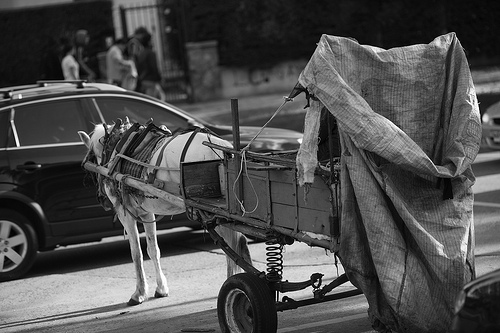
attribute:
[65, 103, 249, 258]
horse — white, standing, light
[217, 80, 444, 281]
cart — small, wooden, old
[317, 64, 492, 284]
bag — large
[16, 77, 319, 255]
car — dark, shiny, black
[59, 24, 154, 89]
people — walking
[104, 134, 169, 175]
harness — bulky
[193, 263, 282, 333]
tire — black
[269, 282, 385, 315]
axle — metal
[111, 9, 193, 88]
gate — metal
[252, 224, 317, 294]
springs — shocks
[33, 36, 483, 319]
picture — black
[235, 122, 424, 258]
buggy — wood